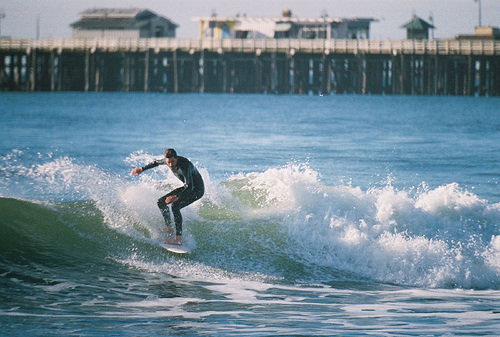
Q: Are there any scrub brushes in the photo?
A: No, there are no scrub brushes.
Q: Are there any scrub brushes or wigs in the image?
A: No, there are no scrub brushes or wigs.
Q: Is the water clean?
A: Yes, the water is clean.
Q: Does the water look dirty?
A: No, the water is clean.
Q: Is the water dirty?
A: No, the water is clean.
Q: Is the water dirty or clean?
A: The water is clean.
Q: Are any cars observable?
A: No, there are no cars.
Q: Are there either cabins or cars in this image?
A: No, there are no cars or cabins.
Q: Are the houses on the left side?
A: Yes, the houses are on the left of the image.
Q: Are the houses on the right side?
A: No, the houses are on the left of the image.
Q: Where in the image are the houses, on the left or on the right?
A: The houses are on the left of the image.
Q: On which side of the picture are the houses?
A: The houses are on the left of the image.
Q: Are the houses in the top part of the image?
A: Yes, the houses are in the top of the image.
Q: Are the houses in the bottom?
A: No, the houses are in the top of the image.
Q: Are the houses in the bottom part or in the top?
A: The houses are in the top of the image.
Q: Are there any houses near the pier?
A: Yes, there are houses near the pier.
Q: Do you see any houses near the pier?
A: Yes, there are houses near the pier.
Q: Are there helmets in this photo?
A: No, there are no helmets.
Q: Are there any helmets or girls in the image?
A: No, there are no helmets or girls.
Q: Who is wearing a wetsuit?
A: The man is wearing a wetsuit.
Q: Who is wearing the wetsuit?
A: The man is wearing a wetsuit.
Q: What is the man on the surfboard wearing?
A: The man is wearing a wet suit.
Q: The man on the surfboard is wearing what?
A: The man is wearing a wet suit.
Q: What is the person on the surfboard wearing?
A: The man is wearing a wet suit.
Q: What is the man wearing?
A: The man is wearing a wet suit.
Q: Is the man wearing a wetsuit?
A: Yes, the man is wearing a wetsuit.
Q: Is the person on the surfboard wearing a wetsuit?
A: Yes, the man is wearing a wetsuit.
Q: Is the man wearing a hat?
A: No, the man is wearing a wetsuit.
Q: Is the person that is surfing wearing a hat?
A: No, the man is wearing a wetsuit.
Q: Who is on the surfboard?
A: The man is on the surfboard.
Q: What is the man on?
A: The man is on the surfboard.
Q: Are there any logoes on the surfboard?
A: No, there is a man on the surfboard.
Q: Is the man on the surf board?
A: Yes, the man is on the surf board.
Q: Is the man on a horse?
A: No, the man is on the surf board.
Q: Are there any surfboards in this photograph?
A: Yes, there is a surfboard.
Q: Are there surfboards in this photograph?
A: Yes, there is a surfboard.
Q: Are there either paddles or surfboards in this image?
A: Yes, there is a surfboard.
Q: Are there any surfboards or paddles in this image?
A: Yes, there is a surfboard.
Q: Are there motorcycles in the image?
A: No, there are no motorcycles.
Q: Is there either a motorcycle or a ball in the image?
A: No, there are no motorcycles or balls.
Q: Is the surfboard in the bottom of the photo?
A: Yes, the surfboard is in the bottom of the image.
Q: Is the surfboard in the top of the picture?
A: No, the surfboard is in the bottom of the image.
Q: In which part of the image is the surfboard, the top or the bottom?
A: The surfboard is in the bottom of the image.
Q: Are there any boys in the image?
A: No, there are no boys.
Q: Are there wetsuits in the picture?
A: Yes, there is a wetsuit.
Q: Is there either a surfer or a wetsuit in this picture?
A: Yes, there is a wetsuit.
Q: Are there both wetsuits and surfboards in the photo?
A: Yes, there are both a wetsuit and a surfboard.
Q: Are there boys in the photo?
A: No, there are no boys.